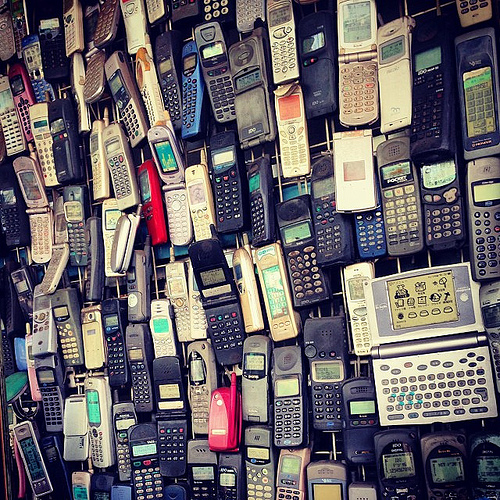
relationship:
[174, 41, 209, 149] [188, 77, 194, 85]
handset has button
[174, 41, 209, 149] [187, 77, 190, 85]
handset has button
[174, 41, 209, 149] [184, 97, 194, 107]
handset has button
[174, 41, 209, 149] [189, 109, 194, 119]
handset has button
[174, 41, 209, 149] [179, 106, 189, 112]
handset has button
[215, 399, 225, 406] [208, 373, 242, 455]
white button on cellphone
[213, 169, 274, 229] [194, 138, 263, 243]
buttons on cell phone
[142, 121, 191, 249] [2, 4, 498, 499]
phone on wall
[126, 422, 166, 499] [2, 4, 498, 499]
cell phone on wall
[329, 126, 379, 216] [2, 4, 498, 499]
cellphone on wall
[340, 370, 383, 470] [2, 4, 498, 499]
cellphone on wall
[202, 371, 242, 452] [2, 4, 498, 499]
cellphone on wall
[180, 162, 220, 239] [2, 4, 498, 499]
cellphone on wall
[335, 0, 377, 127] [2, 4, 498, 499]
cellphone on wall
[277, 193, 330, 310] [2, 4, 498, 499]
cell phone on wall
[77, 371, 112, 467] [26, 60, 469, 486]
phone on wall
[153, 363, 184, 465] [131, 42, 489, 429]
phone on wall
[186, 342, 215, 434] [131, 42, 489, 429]
phone on wall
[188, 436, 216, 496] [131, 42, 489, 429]
phone on wall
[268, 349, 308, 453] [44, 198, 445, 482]
phone on wall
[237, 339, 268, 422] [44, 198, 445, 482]
phone on wall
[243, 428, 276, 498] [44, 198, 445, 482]
phone on wall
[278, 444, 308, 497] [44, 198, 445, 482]
phone on wall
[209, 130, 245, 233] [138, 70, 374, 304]
phone on wall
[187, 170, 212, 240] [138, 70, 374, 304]
phone on wall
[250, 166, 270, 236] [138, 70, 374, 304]
phone on wall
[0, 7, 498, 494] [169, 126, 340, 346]
phones on wall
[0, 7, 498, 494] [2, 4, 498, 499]
phones on wall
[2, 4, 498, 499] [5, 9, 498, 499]
wall of cellphones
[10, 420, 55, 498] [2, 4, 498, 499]
cell phone on wall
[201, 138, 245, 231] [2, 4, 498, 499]
cellphone on wall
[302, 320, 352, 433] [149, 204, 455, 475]
phone on wall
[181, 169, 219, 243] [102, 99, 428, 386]
phone on wall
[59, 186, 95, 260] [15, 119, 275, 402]
cell phone on wall